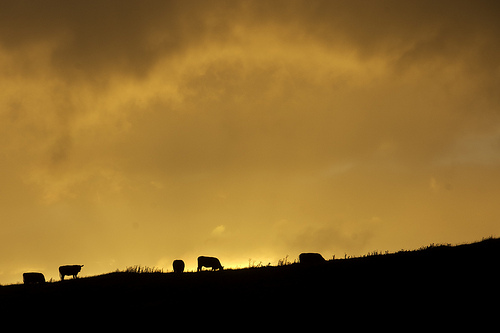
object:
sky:
[3, 4, 483, 259]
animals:
[57, 263, 86, 281]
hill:
[1, 229, 498, 331]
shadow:
[17, 273, 466, 291]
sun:
[204, 218, 285, 271]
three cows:
[58, 252, 329, 281]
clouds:
[73, 54, 434, 185]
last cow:
[298, 250, 330, 264]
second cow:
[196, 255, 226, 270]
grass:
[109, 265, 166, 276]